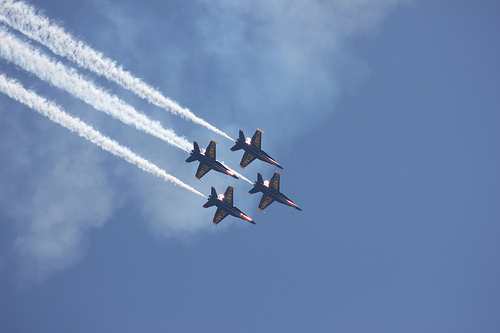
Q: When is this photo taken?
A: Daytime.